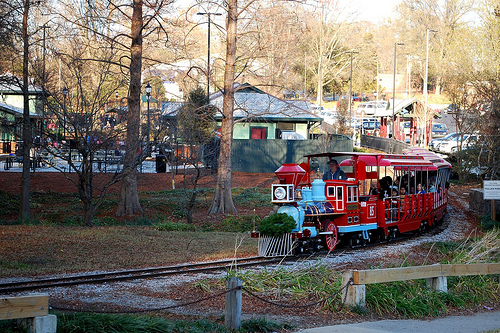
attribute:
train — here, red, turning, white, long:
[250, 134, 454, 257]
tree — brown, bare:
[0, 0, 499, 217]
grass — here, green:
[2, 187, 274, 233]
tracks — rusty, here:
[0, 253, 297, 293]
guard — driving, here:
[320, 160, 347, 183]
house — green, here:
[160, 82, 325, 141]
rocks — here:
[0, 188, 468, 325]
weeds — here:
[445, 223, 500, 265]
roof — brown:
[373, 99, 442, 117]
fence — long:
[339, 263, 500, 305]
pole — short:
[392, 41, 405, 141]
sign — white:
[482, 180, 500, 200]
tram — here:
[373, 99, 442, 148]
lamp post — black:
[197, 11, 222, 107]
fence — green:
[202, 133, 355, 172]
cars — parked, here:
[432, 133, 479, 154]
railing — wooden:
[351, 263, 500, 284]